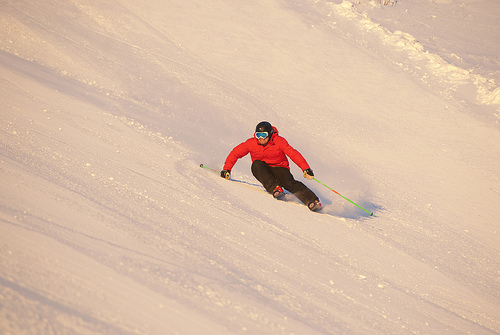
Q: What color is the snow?
A: White.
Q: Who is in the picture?
A: A man.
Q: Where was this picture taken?
A: A ski slope.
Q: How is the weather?
A: Clear.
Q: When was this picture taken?
A: Daytime.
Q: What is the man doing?
A: Skiing.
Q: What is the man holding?
A: Poles.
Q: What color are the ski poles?
A: Yellow.